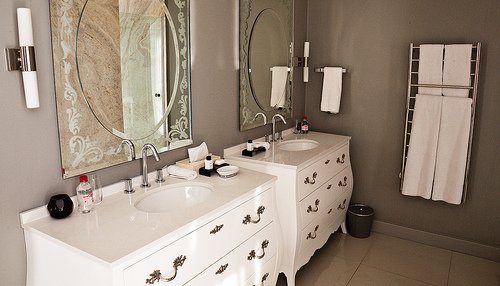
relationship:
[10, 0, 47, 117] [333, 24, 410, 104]
lamp on wall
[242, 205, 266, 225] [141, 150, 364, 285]
silver handle on drawers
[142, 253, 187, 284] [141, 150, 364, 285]
silver handle on drawers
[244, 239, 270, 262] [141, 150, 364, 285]
silver handle on drawers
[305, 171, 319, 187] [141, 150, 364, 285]
silver handle on drawers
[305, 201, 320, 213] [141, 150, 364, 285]
silver handle on drawers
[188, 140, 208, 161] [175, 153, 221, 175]
tissues on box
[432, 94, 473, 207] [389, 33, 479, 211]
towel on wood cabinets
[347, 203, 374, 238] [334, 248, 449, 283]
bin on floor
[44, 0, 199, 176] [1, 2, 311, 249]
mirror on wall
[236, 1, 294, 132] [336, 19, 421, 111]
mirror on wall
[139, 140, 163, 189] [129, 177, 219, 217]
faucet above sink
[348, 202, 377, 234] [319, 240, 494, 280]
bin on floor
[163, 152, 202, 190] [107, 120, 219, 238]
box on sink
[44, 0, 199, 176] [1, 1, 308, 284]
mirror on wall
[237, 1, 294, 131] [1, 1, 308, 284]
mirror on wall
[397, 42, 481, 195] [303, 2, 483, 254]
rack hanging on wall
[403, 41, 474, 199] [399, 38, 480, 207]
towels hanging on towel rack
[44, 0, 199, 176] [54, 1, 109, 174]
mirror has an embossed pattern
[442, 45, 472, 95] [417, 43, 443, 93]
towel hanging towel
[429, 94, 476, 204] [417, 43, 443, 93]
towel hanging towel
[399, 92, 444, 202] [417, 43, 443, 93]
towel hanging towel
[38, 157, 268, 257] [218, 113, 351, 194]
sink beside sink